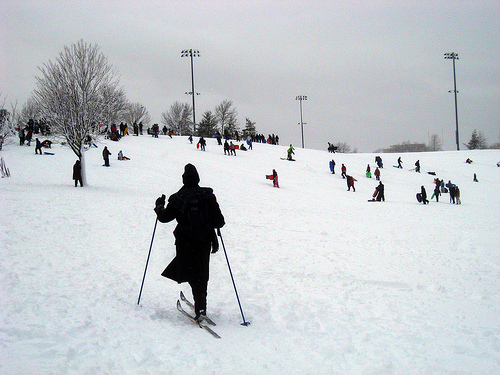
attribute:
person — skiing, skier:
[135, 159, 258, 340]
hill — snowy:
[13, 135, 497, 375]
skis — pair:
[174, 289, 221, 342]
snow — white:
[8, 127, 490, 374]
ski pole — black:
[136, 194, 167, 306]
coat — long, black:
[154, 185, 226, 283]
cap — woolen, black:
[180, 164, 203, 184]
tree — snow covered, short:
[36, 36, 128, 186]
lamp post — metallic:
[179, 48, 204, 137]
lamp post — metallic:
[297, 93, 309, 151]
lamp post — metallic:
[444, 50, 462, 151]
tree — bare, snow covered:
[163, 103, 196, 137]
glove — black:
[156, 197, 166, 208]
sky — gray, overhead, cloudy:
[3, 4, 499, 148]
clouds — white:
[0, 2, 499, 145]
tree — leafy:
[199, 112, 221, 140]